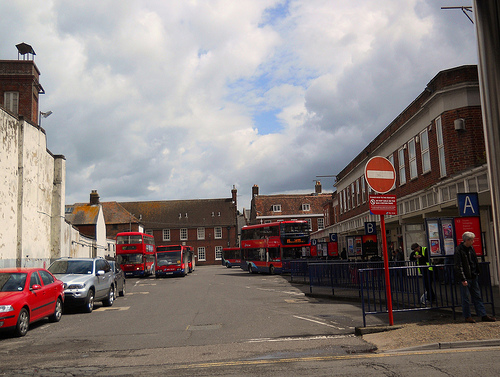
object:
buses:
[115, 220, 310, 277]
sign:
[364, 155, 398, 215]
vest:
[415, 247, 433, 274]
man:
[455, 231, 498, 323]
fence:
[291, 260, 495, 327]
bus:
[115, 232, 155, 277]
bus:
[240, 220, 311, 274]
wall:
[0, 108, 324, 267]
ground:
[0, 264, 498, 376]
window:
[324, 116, 446, 226]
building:
[0, 0, 500, 286]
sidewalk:
[362, 319, 499, 354]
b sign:
[365, 221, 377, 234]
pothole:
[187, 322, 223, 331]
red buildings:
[320, 64, 499, 286]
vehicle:
[46, 256, 126, 313]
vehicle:
[109, 232, 156, 277]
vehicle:
[154, 244, 195, 276]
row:
[0, 232, 195, 339]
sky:
[0, 16, 479, 202]